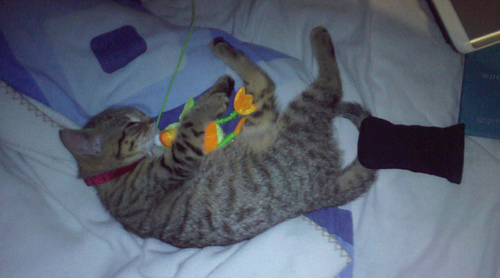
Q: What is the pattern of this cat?
A: Black and gray tabby.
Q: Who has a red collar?
A: The cat.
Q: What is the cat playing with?
A: Toy.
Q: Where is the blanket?
A: Under the cat.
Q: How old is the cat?
A: It appears to be a kitten.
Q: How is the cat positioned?
A: On it's side.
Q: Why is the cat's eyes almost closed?
A: Cat is napping.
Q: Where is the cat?
A: On blanket.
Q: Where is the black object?
A: On cat's tail.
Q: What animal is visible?
A: Cat.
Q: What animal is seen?
A: Cat.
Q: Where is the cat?
A: On bed.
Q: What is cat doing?
A: Laying.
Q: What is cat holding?
A: Toy.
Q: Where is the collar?
A: On cat.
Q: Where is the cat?
A: On bed.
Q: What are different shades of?
A: Blue.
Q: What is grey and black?
A: The cat.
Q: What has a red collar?
A: The cat.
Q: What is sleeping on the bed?
A: A cat.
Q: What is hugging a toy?
A: The cat.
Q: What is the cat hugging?
A: A toy.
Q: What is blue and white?
A: The bedspread.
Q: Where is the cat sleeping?
A: On a bed.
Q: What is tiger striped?
A: The cat.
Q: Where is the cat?
A: In the bedroom.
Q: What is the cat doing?
A: Sleeping.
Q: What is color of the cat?
A: Gray.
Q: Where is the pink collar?
A: Around the cat's neck.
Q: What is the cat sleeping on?
A: A bed.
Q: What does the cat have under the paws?
A: A toy.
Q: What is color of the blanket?
A: White.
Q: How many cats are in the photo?
A: One.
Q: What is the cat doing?
A: Playing with a toy.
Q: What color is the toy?
A: Orange and green.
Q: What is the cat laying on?
A: A blanket.